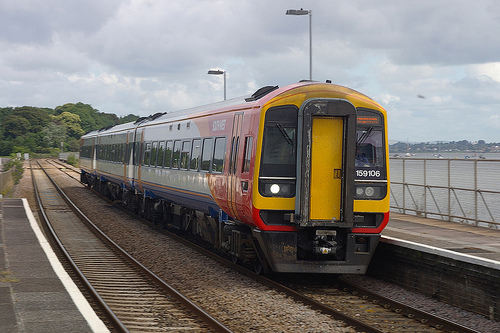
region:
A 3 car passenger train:
[67, 70, 447, 275]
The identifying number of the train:
[348, 165, 385, 182]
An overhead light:
[277, 5, 322, 80]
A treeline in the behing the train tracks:
[2, 102, 156, 169]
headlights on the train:
[261, 175, 388, 205]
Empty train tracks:
[25, 155, 229, 332]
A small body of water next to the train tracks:
[390, 151, 497, 226]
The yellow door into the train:
[305, 113, 347, 222]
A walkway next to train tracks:
[383, 210, 498, 318]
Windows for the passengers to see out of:
[79, 135, 232, 174]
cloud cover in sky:
[0, 0, 497, 141]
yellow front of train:
[77, 82, 387, 272]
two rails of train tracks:
[27, 157, 229, 331]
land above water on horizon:
[388, 139, 498, 160]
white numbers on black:
[355, 165, 385, 179]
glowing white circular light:
[262, 179, 287, 196]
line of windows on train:
[80, 133, 252, 173]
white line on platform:
[385, 226, 498, 267]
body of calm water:
[391, 151, 498, 228]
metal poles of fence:
[386, 157, 498, 230]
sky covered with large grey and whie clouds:
[51, 18, 204, 75]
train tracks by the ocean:
[41, 46, 484, 304]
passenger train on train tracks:
[52, 85, 399, 275]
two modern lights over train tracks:
[199, 3, 326, 103]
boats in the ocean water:
[392, 139, 498, 165]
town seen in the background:
[385, 128, 498, 154]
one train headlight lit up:
[260, 175, 294, 207]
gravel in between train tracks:
[130, 248, 222, 295]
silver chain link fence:
[426, 146, 496, 221]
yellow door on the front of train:
[293, 95, 368, 232]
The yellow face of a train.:
[254, 83, 386, 213]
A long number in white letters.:
[353, 168, 385, 180]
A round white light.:
[268, 182, 281, 196]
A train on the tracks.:
[76, 79, 393, 279]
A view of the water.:
[386, 150, 497, 229]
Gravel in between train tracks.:
[38, 156, 365, 331]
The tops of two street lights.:
[205, 6, 325, 99]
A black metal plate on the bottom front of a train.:
[255, 228, 383, 275]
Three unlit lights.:
[280, 181, 376, 199]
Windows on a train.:
[77, 133, 253, 175]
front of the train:
[231, 70, 416, 230]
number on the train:
[349, 159, 386, 184]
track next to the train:
[73, 244, 170, 312]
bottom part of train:
[131, 175, 240, 251]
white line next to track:
[33, 236, 68, 278]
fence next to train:
[415, 150, 475, 227]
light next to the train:
[270, 2, 328, 78]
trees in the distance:
[24, 103, 76, 143]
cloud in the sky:
[81, 23, 153, 68]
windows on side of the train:
[114, 117, 259, 188]